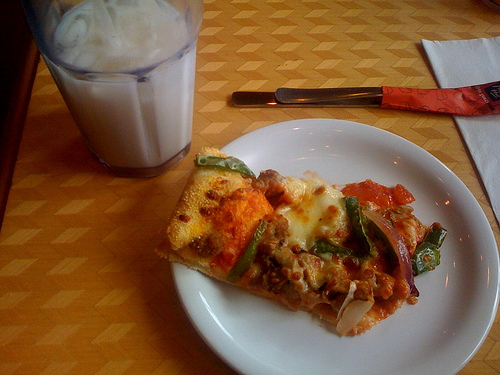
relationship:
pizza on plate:
[167, 144, 433, 315] [171, 117, 494, 375]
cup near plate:
[16, 4, 205, 175] [171, 117, 494, 375]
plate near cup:
[171, 117, 494, 375] [16, 4, 205, 175]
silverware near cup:
[228, 69, 496, 126] [16, 4, 205, 175]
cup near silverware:
[16, 4, 205, 175] [228, 69, 496, 126]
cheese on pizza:
[272, 170, 355, 246] [181, 126, 444, 320]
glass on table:
[35, 8, 225, 180] [2, 13, 496, 371]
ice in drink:
[55, 24, 164, 71] [61, 6, 202, 167]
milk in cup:
[52, 11, 195, 167] [42, 17, 209, 180]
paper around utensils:
[364, 57, 498, 124] [224, 70, 496, 108]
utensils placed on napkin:
[228, 84, 498, 118] [412, 33, 499, 240]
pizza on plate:
[167, 144, 433, 315] [161, 124, 462, 373]